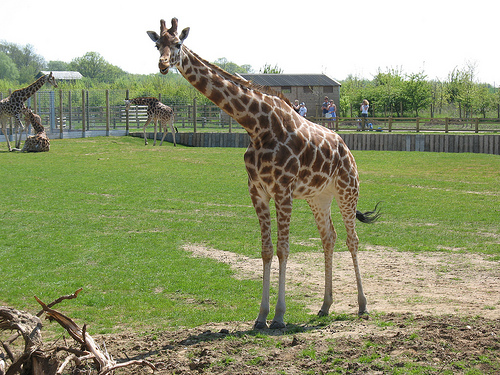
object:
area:
[1, 116, 451, 359]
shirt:
[362, 104, 369, 113]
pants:
[362, 113, 369, 127]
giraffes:
[0, 70, 59, 152]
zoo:
[1, 87, 500, 375]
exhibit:
[0, 16, 383, 330]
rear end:
[326, 128, 384, 224]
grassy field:
[68, 137, 245, 333]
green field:
[98, 222, 243, 328]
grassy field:
[108, 142, 247, 332]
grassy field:
[348, 150, 500, 333]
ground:
[95, 140, 246, 371]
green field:
[0, 139, 77, 341]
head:
[146, 17, 191, 76]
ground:
[382, 152, 484, 372]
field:
[0, 132, 500, 375]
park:
[0, 39, 500, 373]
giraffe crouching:
[10, 106, 51, 153]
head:
[46, 71, 58, 88]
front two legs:
[246, 175, 293, 322]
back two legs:
[305, 181, 368, 306]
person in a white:
[360, 99, 370, 131]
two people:
[321, 96, 336, 132]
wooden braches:
[0, 89, 233, 140]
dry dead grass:
[306, 248, 426, 306]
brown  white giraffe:
[146, 17, 384, 330]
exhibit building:
[219, 71, 342, 121]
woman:
[323, 99, 337, 132]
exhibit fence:
[302, 116, 499, 135]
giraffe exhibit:
[0, 4, 410, 351]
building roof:
[228, 72, 343, 87]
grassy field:
[0, 137, 132, 269]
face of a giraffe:
[154, 32, 182, 75]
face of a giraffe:
[48, 72, 59, 88]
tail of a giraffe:
[355, 199, 382, 223]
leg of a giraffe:
[152, 118, 158, 144]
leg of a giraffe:
[268, 191, 293, 319]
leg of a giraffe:
[333, 172, 368, 310]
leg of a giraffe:
[306, 194, 339, 309]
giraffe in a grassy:
[53, 184, 172, 274]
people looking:
[287, 95, 372, 132]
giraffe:
[124, 97, 180, 147]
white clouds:
[256, 6, 344, 49]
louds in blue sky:
[53, 1, 139, 62]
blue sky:
[0, 0, 500, 88]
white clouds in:
[219, 6, 332, 48]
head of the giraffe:
[124, 97, 132, 111]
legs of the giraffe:
[246, 178, 273, 319]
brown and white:
[249, 97, 325, 192]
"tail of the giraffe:
[173, 113, 179, 134]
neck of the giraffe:
[180, 50, 267, 136]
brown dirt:
[308, 307, 500, 375]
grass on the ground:
[349, 233, 478, 326]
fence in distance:
[331, 95, 498, 150]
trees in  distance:
[399, 70, 432, 122]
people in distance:
[291, 96, 370, 133]